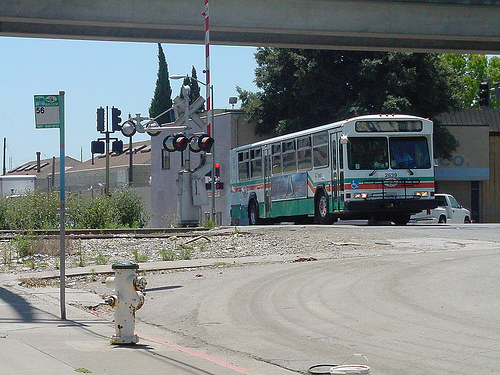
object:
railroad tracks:
[0, 228, 200, 238]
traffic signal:
[214, 163, 221, 182]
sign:
[34, 94, 59, 128]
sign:
[437, 155, 465, 166]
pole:
[175, 98, 202, 225]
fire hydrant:
[104, 260, 148, 344]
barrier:
[200, 0, 211, 134]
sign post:
[34, 90, 65, 158]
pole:
[57, 92, 66, 321]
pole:
[210, 84, 215, 226]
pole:
[1, 138, 8, 176]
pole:
[35, 150, 41, 173]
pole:
[106, 130, 110, 196]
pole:
[128, 135, 134, 186]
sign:
[173, 95, 206, 131]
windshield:
[347, 136, 432, 170]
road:
[0, 225, 498, 374]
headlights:
[354, 192, 368, 199]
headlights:
[414, 191, 428, 197]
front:
[342, 113, 436, 213]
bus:
[228, 113, 437, 226]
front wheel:
[315, 191, 336, 225]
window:
[281, 139, 298, 172]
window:
[297, 137, 312, 169]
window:
[312, 132, 330, 166]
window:
[250, 149, 262, 179]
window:
[237, 151, 249, 180]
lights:
[161, 132, 225, 190]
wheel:
[248, 197, 260, 225]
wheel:
[390, 213, 411, 225]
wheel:
[439, 215, 446, 224]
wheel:
[464, 216, 472, 224]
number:
[385, 172, 397, 177]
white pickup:
[408, 193, 472, 224]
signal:
[214, 163, 221, 168]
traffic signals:
[96, 107, 105, 131]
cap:
[111, 261, 140, 269]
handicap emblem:
[351, 179, 359, 189]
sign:
[270, 171, 309, 203]